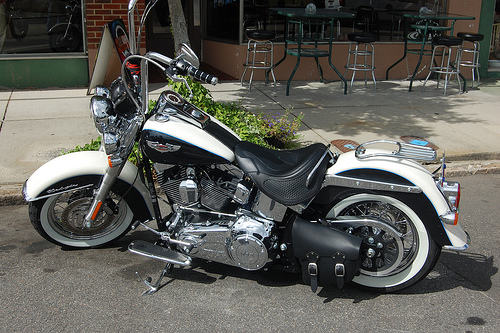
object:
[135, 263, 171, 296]
kick stand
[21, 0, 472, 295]
motorcycle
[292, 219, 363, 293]
bad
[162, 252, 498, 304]
shadow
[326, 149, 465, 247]
fender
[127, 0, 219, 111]
handlebars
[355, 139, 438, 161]
rack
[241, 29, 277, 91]
chairs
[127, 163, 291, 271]
chrome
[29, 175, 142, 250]
tire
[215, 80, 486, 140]
shadow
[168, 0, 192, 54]
tree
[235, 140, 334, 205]
cushion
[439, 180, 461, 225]
tail light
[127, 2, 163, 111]
windshield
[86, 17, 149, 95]
sandwich board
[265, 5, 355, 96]
table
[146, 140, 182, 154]
logo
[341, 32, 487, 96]
stools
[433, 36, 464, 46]
seats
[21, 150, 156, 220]
fender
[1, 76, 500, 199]
sidewalk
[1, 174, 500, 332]
street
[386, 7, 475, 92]
table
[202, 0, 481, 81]
wall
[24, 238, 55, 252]
spot